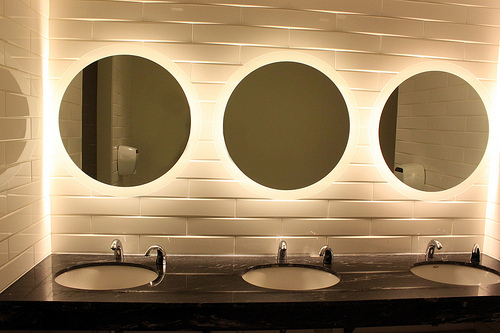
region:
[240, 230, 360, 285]
the tap is silver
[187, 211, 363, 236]
the wall is white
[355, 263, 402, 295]
the surface is black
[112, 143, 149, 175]
the soap dispenser is white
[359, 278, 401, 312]
the surface is made of concrete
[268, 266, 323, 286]
the sink is white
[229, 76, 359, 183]
the mirror is circle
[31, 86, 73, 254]
the corner has light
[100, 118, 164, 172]
there is refection in the mirror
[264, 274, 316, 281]
the sink is shiny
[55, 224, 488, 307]
Three sinks in the bathroom.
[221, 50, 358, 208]
Mirror on the wall.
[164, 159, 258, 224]
Tile on the bathroom wall.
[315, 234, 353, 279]
Automatic soap dispenser.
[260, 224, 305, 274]
Faucet in the bathroom.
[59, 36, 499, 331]
Three mirror on the bathroom wall.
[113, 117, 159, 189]
Hand dryer.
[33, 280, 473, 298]
Marble vanity top.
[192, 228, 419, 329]
Bathroom automatic faucet.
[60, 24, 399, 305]
Bathroom with subway tile.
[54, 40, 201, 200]
circular restroom mirror on left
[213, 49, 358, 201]
circular restroom mirror in center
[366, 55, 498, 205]
circular restroom mirror on right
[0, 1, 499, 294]
white subway ceramic tiles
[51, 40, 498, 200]
three circular restroom mirrors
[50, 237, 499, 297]
three restroom sinks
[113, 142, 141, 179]
hand dryer reflected in mirror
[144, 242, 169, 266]
automatic soap dispenser for left sink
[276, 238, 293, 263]
water tap for center sink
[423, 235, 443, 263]
water tap for right sink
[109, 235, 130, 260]
Faucet on the left belonging to the first sink.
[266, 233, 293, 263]
Faucet in the center belonging to the center sink.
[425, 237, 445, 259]
Faucet spout on the left belonging to the third sink.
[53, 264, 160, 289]
First round sink on the black counter.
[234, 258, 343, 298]
Middle round sink on the black counter.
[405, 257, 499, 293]
Last round sink on the black counter.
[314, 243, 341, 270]
Faucet spout on the right belonging to the middle sink.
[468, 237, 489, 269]
Faucet spout on the right belonging to the last sink.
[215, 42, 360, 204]
Circular mirror in the middle.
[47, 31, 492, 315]
This is a bathroom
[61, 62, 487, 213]
There are 3 mirrors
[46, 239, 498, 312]
There are 3 sinks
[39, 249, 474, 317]
The counter is black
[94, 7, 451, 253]
The wall is white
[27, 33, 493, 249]
There are lights behind the mirrors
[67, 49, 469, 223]
The mirrors are round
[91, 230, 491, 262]
The faucets are silver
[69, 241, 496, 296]
The sinks are round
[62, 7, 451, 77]
The bricks are rectangular